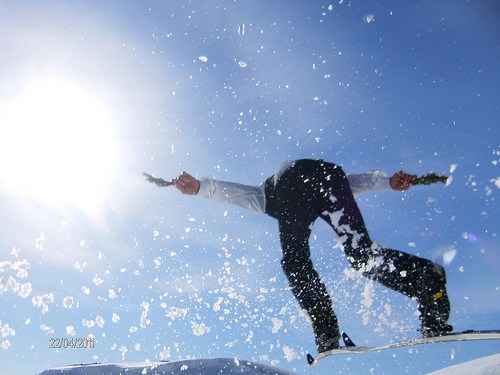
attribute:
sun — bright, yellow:
[3, 75, 140, 259]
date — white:
[45, 333, 102, 352]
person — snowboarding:
[176, 165, 486, 345]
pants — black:
[275, 182, 419, 332]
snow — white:
[118, 247, 259, 320]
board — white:
[297, 323, 494, 370]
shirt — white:
[206, 171, 274, 215]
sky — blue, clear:
[145, 26, 431, 101]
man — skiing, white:
[187, 154, 455, 327]